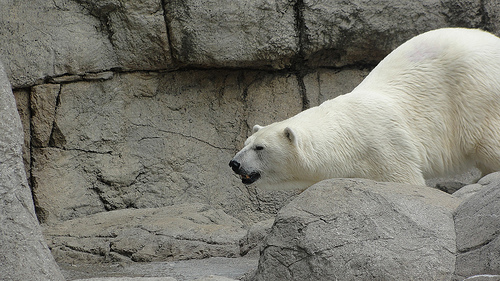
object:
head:
[228, 121, 299, 186]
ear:
[283, 127, 298, 143]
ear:
[253, 124, 261, 132]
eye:
[256, 147, 263, 150]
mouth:
[236, 167, 261, 184]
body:
[279, 27, 499, 177]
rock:
[0, 0, 171, 89]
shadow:
[127, 48, 340, 96]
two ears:
[252, 124, 298, 143]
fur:
[416, 109, 459, 159]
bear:
[229, 28, 500, 187]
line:
[291, 0, 308, 109]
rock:
[163, 0, 300, 70]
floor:
[66, 257, 265, 279]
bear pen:
[2, 2, 498, 276]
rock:
[300, 0, 486, 70]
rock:
[454, 177, 500, 281]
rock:
[248, 177, 461, 280]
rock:
[30, 68, 364, 224]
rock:
[43, 203, 266, 270]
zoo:
[0, 0, 499, 281]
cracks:
[22, 74, 89, 232]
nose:
[229, 160, 242, 171]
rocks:
[0, 61, 56, 278]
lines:
[161, 0, 177, 68]